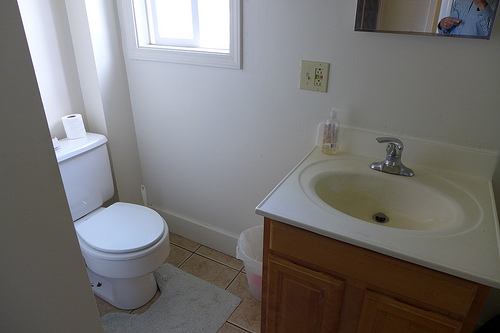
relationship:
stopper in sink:
[374, 207, 389, 222] [253, 120, 498, 285]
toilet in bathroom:
[36, 118, 181, 315] [9, 1, 498, 328]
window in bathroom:
[128, 0, 235, 62] [9, 1, 498, 328]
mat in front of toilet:
[87, 265, 257, 332] [50, 129, 170, 309]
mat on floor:
[87, 265, 257, 332] [172, 232, 243, 322]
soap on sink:
[320, 105, 343, 155] [323, 162, 486, 227]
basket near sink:
[231, 224, 263, 301] [253, 120, 498, 285]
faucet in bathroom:
[372, 133, 411, 173] [9, 1, 498, 328]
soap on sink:
[320, 105, 343, 155] [248, 125, 479, 254]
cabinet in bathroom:
[258, 214, 490, 331] [9, 1, 498, 328]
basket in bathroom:
[231, 224, 263, 301] [9, 1, 498, 328]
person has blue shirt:
[431, 0, 498, 45] [448, 3, 493, 37]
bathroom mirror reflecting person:
[351, 0, 498, 40] [431, 0, 498, 45]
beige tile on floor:
[173, 238, 215, 269] [89, 230, 271, 330]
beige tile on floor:
[176, 248, 226, 273] [173, 240, 225, 328]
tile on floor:
[167, 244, 255, 289] [89, 230, 271, 330]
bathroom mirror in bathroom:
[351, 0, 498, 40] [9, 1, 498, 328]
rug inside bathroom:
[99, 250, 238, 331] [9, 1, 498, 328]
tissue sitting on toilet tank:
[59, 109, 87, 139] [45, 127, 123, 228]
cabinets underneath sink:
[261, 243, 364, 330] [356, 166, 466, 239]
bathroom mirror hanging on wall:
[351, 0, 498, 40] [250, 46, 497, 93]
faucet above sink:
[372, 133, 411, 173] [297, 157, 483, 237]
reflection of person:
[357, 1, 490, 38] [435, 0, 495, 36]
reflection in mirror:
[357, 1, 490, 38] [354, 0, 496, 42]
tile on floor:
[157, 230, 206, 256] [89, 230, 271, 330]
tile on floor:
[192, 244, 243, 274] [89, 230, 271, 330]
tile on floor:
[160, 242, 192, 268] [89, 230, 271, 330]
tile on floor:
[167, 251, 243, 289] [89, 230, 271, 330]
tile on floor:
[212, 267, 259, 331] [89, 230, 271, 330]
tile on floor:
[157, 239, 240, 299] [170, 240, 252, 320]